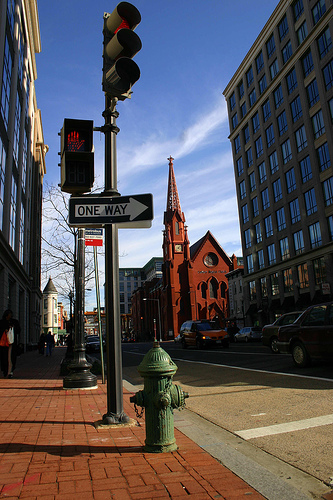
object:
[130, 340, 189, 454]
fire hydrant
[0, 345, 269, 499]
sidewalk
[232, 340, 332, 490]
lines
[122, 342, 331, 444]
lines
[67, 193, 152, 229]
sign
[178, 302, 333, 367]
traffic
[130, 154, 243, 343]
church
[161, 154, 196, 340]
tower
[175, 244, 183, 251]
clock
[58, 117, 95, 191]
indicator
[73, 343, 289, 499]
roadside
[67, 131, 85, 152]
hand signal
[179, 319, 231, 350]
van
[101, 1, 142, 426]
traffic light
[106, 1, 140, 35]
light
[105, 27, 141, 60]
light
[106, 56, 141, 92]
light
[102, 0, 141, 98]
three lights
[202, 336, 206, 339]
turn signal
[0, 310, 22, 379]
woman's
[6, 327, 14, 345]
bag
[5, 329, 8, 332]
hand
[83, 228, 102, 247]
sign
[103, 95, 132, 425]
pole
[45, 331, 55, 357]
people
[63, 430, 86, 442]
brick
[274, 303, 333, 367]
car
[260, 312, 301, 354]
car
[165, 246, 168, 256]
clock